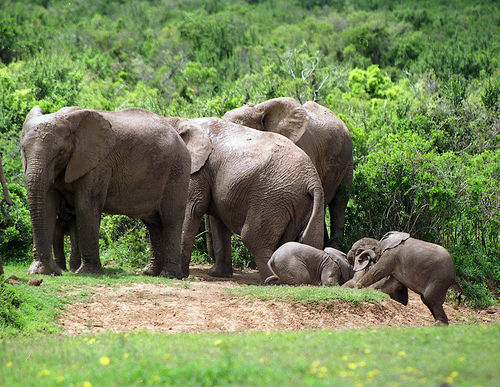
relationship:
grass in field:
[158, 336, 193, 348] [10, 263, 498, 382]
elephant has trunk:
[20, 104, 185, 281] [22, 161, 60, 263]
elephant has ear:
[356, 233, 454, 325] [378, 234, 409, 246]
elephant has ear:
[20, 104, 185, 281] [60, 109, 117, 185]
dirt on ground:
[77, 281, 448, 345] [10, 263, 498, 382]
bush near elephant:
[429, 153, 492, 252] [356, 233, 454, 325]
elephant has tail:
[165, 114, 324, 278] [294, 174, 325, 243]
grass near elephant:
[158, 336, 193, 348] [165, 114, 324, 278]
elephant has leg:
[20, 104, 185, 281] [74, 200, 101, 278]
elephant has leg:
[20, 104, 185, 281] [158, 200, 187, 275]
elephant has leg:
[165, 114, 324, 278] [204, 204, 234, 279]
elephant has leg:
[356, 233, 454, 325] [425, 287, 451, 330]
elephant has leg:
[165, 114, 324, 278] [182, 199, 203, 265]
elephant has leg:
[223, 93, 350, 245] [332, 184, 346, 244]